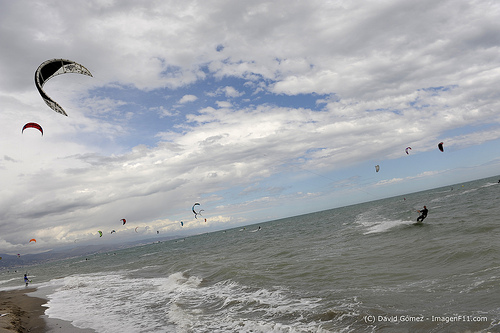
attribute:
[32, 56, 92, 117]
kite — large, black, white, curved, flying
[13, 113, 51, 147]
kite — red, white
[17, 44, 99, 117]
kite — black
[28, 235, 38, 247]
kite — very orange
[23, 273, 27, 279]
shirt — blue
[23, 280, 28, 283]
shorts — white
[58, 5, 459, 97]
white clouds — white 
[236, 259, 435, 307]
water — grayish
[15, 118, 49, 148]
kite — red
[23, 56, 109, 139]
kite — black and white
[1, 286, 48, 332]
beach — brown, sandy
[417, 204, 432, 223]
wetsuit — black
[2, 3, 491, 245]
clouds — white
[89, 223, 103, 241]
kite — green, orange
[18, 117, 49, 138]
kite — red, black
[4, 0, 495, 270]
sky — blue, cloudy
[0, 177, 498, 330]
water — grey, white, rough, brown , ocean 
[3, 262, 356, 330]
water — white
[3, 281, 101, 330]
sand — brown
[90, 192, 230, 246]
windsurfing sails — several 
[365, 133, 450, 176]
windsurfing sails — three 